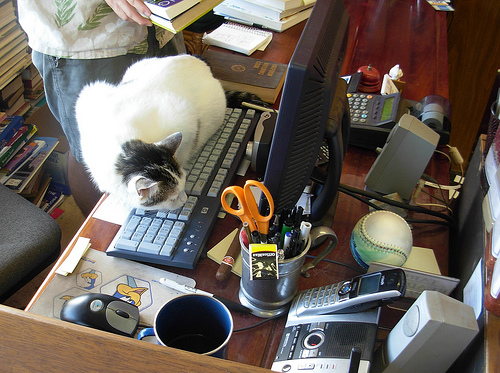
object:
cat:
[75, 53, 228, 212]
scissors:
[219, 179, 277, 243]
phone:
[270, 268, 407, 372]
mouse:
[60, 293, 138, 337]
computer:
[257, 0, 352, 226]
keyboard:
[106, 106, 278, 270]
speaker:
[366, 113, 440, 199]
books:
[8, 131, 60, 191]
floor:
[2, 192, 90, 311]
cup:
[138, 293, 235, 360]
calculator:
[346, 92, 454, 129]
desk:
[25, 0, 451, 370]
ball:
[350, 210, 413, 264]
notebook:
[200, 21, 275, 56]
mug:
[240, 224, 340, 317]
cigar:
[216, 220, 244, 282]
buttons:
[327, 294, 335, 302]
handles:
[221, 178, 276, 233]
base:
[273, 300, 380, 370]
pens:
[279, 232, 294, 256]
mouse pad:
[28, 244, 198, 344]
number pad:
[171, 219, 185, 228]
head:
[123, 131, 189, 213]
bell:
[356, 64, 383, 91]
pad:
[207, 224, 246, 276]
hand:
[106, 1, 152, 28]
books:
[142, 1, 228, 35]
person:
[18, 2, 152, 214]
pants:
[32, 49, 147, 161]